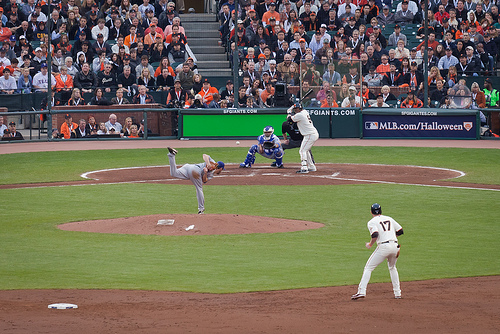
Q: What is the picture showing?
A: It is showing a stadium.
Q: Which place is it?
A: It is a stadium.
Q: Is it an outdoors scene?
A: Yes, it is outdoors.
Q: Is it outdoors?
A: Yes, it is outdoors.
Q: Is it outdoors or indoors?
A: It is outdoors.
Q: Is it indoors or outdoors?
A: It is outdoors.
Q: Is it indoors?
A: No, it is outdoors.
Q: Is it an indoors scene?
A: No, it is outdoors.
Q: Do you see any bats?
A: Yes, there is a bat.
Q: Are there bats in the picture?
A: Yes, there is a bat.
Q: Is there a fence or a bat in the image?
A: Yes, there is a bat.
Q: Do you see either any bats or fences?
A: Yes, there is a bat.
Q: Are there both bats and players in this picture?
A: Yes, there are both a bat and a player.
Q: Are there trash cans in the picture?
A: No, there are no trash cans.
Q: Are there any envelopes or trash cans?
A: No, there are no trash cans or envelopes.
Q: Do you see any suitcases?
A: No, there are no suitcases.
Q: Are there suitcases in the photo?
A: No, there are no suitcases.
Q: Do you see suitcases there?
A: No, there are no suitcases.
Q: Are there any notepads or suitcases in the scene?
A: No, there are no suitcases or notepads.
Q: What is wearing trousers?
A: The pitcher is wearing trousers.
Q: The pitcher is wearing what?
A: The pitcher is wearing pants.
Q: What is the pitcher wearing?
A: The pitcher is wearing pants.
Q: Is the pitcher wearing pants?
A: Yes, the pitcher is wearing pants.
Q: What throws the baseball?
A: The pitcher throws the baseball.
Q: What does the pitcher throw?
A: The pitcher throws the baseball.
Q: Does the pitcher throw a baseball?
A: Yes, the pitcher throws a baseball.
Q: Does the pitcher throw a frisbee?
A: No, the pitcher throws a baseball.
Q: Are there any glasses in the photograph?
A: No, there are no glasses.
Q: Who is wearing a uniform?
A: The batter is wearing a uniform.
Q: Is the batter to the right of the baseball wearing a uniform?
A: Yes, the batter is wearing a uniform.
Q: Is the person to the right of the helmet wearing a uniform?
A: Yes, the batter is wearing a uniform.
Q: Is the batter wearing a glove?
A: No, the batter is wearing a uniform.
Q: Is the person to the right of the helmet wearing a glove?
A: No, the batter is wearing a uniform.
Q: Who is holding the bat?
A: The batter is holding the bat.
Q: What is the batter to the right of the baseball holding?
A: The batter is holding the bat.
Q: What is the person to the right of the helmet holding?
A: The batter is holding the bat.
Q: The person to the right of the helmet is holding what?
A: The batter is holding the bat.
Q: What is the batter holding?
A: The batter is holding the bat.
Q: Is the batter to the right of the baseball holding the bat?
A: Yes, the batter is holding the bat.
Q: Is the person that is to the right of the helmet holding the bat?
A: Yes, the batter is holding the bat.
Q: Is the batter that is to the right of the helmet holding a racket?
A: No, the batter is holding the bat.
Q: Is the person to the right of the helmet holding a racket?
A: No, the batter is holding the bat.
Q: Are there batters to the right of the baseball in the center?
A: Yes, there is a batter to the right of the baseball.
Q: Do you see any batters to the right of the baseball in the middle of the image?
A: Yes, there is a batter to the right of the baseball.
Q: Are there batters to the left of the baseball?
A: No, the batter is to the right of the baseball.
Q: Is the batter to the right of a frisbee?
A: No, the batter is to the right of the baseball.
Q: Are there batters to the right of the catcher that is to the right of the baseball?
A: Yes, there is a batter to the right of the catcher.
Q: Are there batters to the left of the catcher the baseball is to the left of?
A: No, the batter is to the right of the catcher.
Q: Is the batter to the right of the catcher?
A: Yes, the batter is to the right of the catcher.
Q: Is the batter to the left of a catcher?
A: No, the batter is to the right of a catcher.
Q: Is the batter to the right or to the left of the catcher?
A: The batter is to the right of the catcher.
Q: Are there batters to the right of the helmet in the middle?
A: Yes, there is a batter to the right of the helmet.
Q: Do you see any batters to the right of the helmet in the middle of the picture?
A: Yes, there is a batter to the right of the helmet.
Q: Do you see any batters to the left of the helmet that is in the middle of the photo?
A: No, the batter is to the right of the helmet.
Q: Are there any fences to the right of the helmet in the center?
A: No, there is a batter to the right of the helmet.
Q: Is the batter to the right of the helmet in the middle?
A: Yes, the batter is to the right of the helmet.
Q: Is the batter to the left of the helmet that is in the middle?
A: No, the batter is to the right of the helmet.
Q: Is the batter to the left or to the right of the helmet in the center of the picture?
A: The batter is to the right of the helmet.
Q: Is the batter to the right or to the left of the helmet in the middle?
A: The batter is to the right of the helmet.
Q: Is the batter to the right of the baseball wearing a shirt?
A: Yes, the batter is wearing a shirt.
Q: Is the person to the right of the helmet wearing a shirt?
A: Yes, the batter is wearing a shirt.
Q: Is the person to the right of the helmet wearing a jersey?
A: No, the batter is wearing a shirt.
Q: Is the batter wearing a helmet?
A: Yes, the batter is wearing a helmet.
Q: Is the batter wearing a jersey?
A: No, the batter is wearing a helmet.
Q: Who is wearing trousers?
A: The batter is wearing trousers.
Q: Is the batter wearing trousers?
A: Yes, the batter is wearing trousers.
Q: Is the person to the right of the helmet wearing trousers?
A: Yes, the batter is wearing trousers.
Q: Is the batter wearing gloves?
A: No, the batter is wearing trousers.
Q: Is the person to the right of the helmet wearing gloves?
A: No, the batter is wearing trousers.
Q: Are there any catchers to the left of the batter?
A: Yes, there is a catcher to the left of the batter.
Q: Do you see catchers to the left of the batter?
A: Yes, there is a catcher to the left of the batter.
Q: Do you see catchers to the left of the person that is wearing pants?
A: Yes, there is a catcher to the left of the batter.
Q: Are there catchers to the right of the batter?
A: No, the catcher is to the left of the batter.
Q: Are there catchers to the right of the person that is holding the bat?
A: No, the catcher is to the left of the batter.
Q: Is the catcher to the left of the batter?
A: Yes, the catcher is to the left of the batter.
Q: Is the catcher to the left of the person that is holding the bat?
A: Yes, the catcher is to the left of the batter.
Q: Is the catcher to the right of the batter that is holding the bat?
A: No, the catcher is to the left of the batter.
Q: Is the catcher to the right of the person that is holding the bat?
A: No, the catcher is to the left of the batter.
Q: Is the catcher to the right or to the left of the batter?
A: The catcher is to the left of the batter.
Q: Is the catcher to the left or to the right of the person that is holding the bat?
A: The catcher is to the left of the batter.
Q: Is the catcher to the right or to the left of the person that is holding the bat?
A: The catcher is to the left of the batter.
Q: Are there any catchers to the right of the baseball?
A: Yes, there is a catcher to the right of the baseball.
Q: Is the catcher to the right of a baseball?
A: Yes, the catcher is to the right of a baseball.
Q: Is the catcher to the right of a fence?
A: No, the catcher is to the right of a baseball.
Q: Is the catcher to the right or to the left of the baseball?
A: The catcher is to the right of the baseball.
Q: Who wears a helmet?
A: The catcher wears a helmet.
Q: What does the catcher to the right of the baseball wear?
A: The catcher wears a helmet.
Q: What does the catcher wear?
A: The catcher wears a helmet.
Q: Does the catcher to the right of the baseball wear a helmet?
A: Yes, the catcher wears a helmet.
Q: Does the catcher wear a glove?
A: No, the catcher wears a helmet.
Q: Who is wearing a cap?
A: The man is wearing a cap.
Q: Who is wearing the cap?
A: The man is wearing a cap.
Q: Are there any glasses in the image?
A: No, there are no glasses.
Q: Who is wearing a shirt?
A: The man is wearing a shirt.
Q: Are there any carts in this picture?
A: No, there are no carts.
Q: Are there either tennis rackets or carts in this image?
A: No, there are no carts or tennis rackets.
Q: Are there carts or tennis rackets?
A: No, there are no carts or tennis rackets.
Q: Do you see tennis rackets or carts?
A: No, there are no carts or tennis rackets.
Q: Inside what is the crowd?
A: The crowd is inside the stadium.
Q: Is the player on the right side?
A: Yes, the player is on the right of the image.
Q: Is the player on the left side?
A: No, the player is on the right of the image.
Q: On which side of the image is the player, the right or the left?
A: The player is on the right of the image.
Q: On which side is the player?
A: The player is on the right of the image.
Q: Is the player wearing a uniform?
A: Yes, the player is wearing a uniform.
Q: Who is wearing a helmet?
A: The player is wearing a helmet.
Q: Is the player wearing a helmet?
A: Yes, the player is wearing a helmet.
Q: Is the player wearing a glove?
A: No, the player is wearing a helmet.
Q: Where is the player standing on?
A: The player is standing on the field.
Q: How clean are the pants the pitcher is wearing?
A: The pants are dirty.